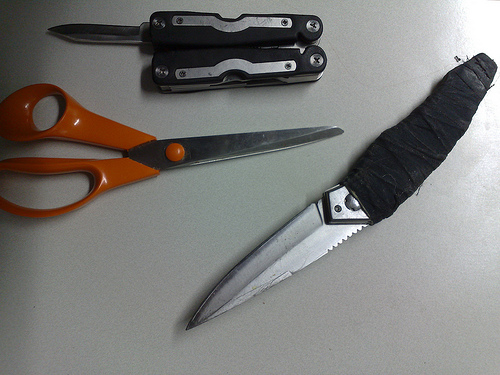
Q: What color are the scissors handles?
A: Orange.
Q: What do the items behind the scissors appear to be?
A: Pocket knives.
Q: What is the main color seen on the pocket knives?
A: Black.